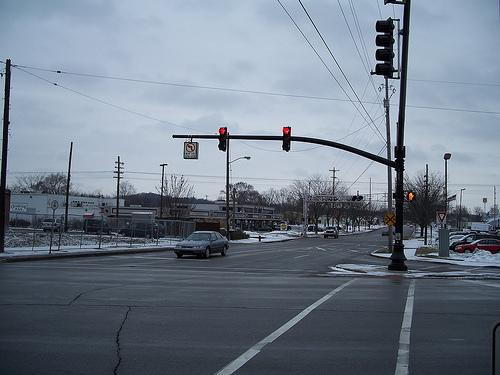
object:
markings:
[214, 277, 417, 375]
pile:
[464, 247, 496, 262]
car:
[456, 238, 500, 254]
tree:
[221, 178, 261, 213]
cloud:
[47, 110, 164, 151]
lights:
[375, 17, 394, 75]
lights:
[217, 127, 293, 152]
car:
[174, 231, 229, 258]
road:
[0, 219, 500, 373]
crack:
[113, 306, 131, 372]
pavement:
[0, 271, 492, 375]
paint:
[206, 274, 417, 374]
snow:
[451, 247, 500, 266]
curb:
[392, 234, 452, 270]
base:
[387, 240, 407, 270]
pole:
[386, 0, 410, 271]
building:
[6, 193, 125, 229]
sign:
[184, 142, 196, 159]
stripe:
[404, 279, 416, 374]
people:
[39, 215, 124, 233]